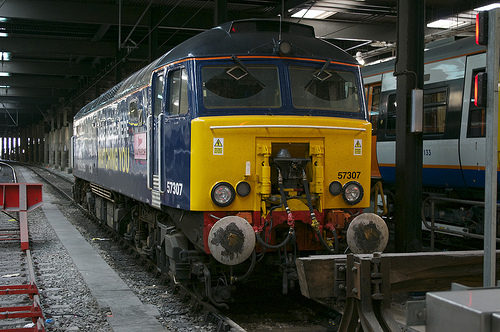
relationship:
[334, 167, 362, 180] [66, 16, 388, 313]
number on blue train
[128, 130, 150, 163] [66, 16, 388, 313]
sign on blue train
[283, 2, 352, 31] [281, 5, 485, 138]
light in area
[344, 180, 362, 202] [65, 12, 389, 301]
headlight on train engine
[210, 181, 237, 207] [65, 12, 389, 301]
headlight on train engine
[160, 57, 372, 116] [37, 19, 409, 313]
windshield on front of train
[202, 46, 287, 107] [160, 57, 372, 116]
wiper attached to windshield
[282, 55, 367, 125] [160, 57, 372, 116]
wiper attached to windshield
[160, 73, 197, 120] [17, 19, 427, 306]
window on front of train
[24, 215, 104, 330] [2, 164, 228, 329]
rocks sitting on ground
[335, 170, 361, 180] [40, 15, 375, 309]
number on front of train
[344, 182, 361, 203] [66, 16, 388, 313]
headlight on front of blue train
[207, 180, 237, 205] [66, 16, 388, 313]
headlight on front of blue train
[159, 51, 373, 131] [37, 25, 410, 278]
windshield on front of train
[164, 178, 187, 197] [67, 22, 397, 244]
numbers printed on side of train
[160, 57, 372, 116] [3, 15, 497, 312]
windshield of train's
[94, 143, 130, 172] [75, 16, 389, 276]
writing on train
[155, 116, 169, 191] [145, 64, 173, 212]
metal handle next to door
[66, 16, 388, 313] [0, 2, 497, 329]
blue train in lot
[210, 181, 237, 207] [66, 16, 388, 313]
headlight on blue train